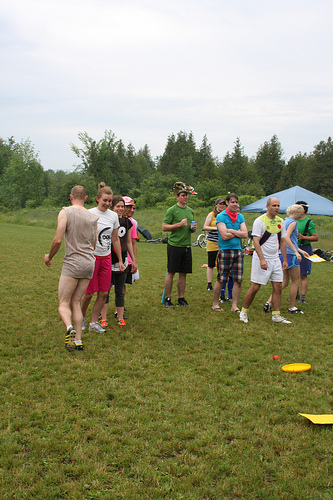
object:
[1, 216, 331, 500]
grass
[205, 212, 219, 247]
top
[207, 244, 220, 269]
shorts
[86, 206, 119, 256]
top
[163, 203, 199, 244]
top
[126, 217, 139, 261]
top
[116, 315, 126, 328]
shoe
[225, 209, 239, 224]
scarf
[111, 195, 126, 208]
hair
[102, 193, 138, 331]
lady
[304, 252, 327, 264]
paper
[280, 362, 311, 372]
frisbee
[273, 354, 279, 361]
ball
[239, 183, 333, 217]
tent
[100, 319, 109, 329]
sneaker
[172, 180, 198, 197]
hat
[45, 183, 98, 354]
person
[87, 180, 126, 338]
person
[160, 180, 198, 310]
person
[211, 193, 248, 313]
person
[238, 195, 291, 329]
person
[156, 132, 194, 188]
tree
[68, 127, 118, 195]
tree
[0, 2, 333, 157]
sky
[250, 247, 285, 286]
shorts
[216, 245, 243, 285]
shorts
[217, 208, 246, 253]
shirt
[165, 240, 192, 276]
shorts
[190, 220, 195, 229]
can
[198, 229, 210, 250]
bicycle